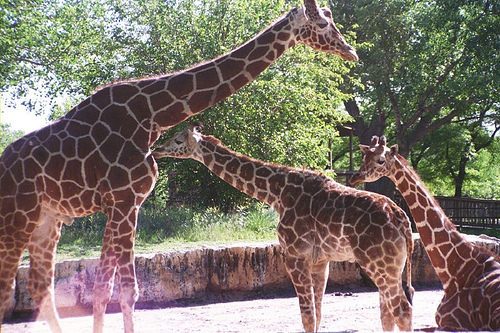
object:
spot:
[251, 175, 270, 192]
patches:
[96, 130, 125, 166]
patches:
[150, 100, 189, 127]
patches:
[126, 93, 152, 121]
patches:
[95, 102, 140, 139]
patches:
[167, 73, 196, 100]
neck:
[394, 153, 479, 280]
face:
[303, 9, 362, 64]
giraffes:
[149, 122, 422, 331]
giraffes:
[349, 134, 497, 328]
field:
[2, 283, 452, 331]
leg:
[378, 294, 393, 331]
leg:
[355, 243, 411, 329]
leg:
[311, 262, 330, 315]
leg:
[288, 262, 318, 332]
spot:
[74, 131, 97, 158]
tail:
[397, 207, 415, 307]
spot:
[114, 140, 148, 171]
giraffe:
[5, 1, 364, 333]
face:
[154, 130, 198, 159]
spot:
[256, 189, 268, 201]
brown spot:
[434, 229, 450, 245]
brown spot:
[310, 189, 330, 219]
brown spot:
[218, 59, 248, 81]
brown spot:
[446, 250, 465, 278]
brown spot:
[106, 162, 131, 192]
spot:
[253, 164, 273, 180]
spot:
[415, 223, 432, 248]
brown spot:
[268, 173, 285, 197]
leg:
[112, 200, 141, 331]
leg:
[90, 214, 120, 332]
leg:
[25, 216, 59, 330]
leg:
[0, 201, 38, 318]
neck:
[212, 127, 299, 204]